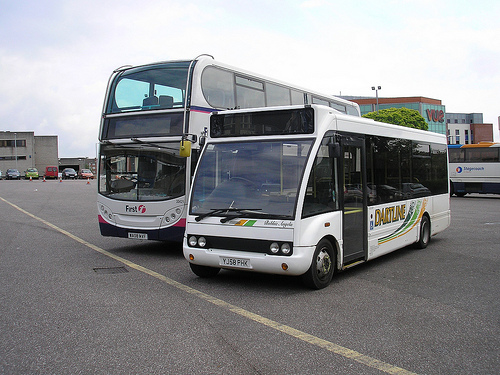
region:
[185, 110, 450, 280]
bus is white with gold letters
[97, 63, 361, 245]
bus is double decker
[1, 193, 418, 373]
yellow line on concrete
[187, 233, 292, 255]
four headlights on bus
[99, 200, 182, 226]
six lights on bus front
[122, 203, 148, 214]
Bus says FIRST on front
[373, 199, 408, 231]
bus says DARTLINE on side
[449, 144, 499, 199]
white bus in background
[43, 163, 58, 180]
red van in background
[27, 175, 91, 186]
orange cones in parking lot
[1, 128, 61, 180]
a tan building on left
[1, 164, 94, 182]
cars on the right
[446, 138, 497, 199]
one bus behind buses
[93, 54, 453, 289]
two buses parked side by side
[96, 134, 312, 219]
windshield of buses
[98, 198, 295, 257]
lights on front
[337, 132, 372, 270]
the side door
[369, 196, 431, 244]
ads on side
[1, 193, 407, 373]
yellow line on street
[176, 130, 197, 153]
rearview mirror on side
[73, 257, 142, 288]
small square spot on the ground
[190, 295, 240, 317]
grease marks on the ground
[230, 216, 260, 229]
yellow and green lines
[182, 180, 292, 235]
pair of black windshield wipers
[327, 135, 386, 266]
black door in the bus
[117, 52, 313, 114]
double decker on the bus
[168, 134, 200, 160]
yellow mirror on side of the bus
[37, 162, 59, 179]
red truck parked in front of building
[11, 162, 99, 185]
vehicles parked in spot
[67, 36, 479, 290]
Two busses parked side by side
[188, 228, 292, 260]
Four small headlights on bus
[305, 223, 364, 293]
Small black tire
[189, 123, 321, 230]
Large square window on bus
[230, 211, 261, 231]
Orange and green logo on front of bus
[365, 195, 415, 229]
Yellow wording on side of bus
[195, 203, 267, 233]
Two black wiper blades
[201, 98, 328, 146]
Black window on top of bus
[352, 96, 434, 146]
Small green tree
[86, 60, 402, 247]
Black and white double decker bus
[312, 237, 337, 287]
Black wheel on front of bus.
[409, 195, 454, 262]
Black wheel on back of bus.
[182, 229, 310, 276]
Lights on front of bus.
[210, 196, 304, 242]
Black wipers on front of bus.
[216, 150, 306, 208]
Large windshield on front of bus.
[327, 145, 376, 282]
Door on side of bus.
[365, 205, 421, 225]
Yellow writing on side of bus.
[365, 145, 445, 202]
Windows line side of bus.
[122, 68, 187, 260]
Large white double decker bus in lot.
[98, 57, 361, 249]
large double decked white bus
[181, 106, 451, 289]
long white metal bus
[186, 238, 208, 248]
small round silver lights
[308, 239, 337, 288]
small round black tire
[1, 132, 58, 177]
large grey stone building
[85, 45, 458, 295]
Two buses side by side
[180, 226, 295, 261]
Four round headlights on a bus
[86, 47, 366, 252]
A white double decker bus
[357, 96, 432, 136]
The top of a green tree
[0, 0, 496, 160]
The sky appears to be overcast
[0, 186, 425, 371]
A white line on the pavement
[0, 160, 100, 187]
A row of parked cars